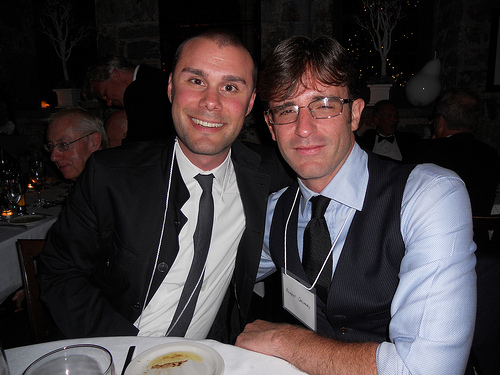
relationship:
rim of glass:
[21, 352, 50, 375] [21, 344, 115, 374]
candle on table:
[0, 208, 13, 218] [0, 179, 73, 302]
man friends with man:
[235, 36, 476, 374] [39, 24, 296, 346]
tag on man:
[280, 268, 317, 332] [235, 36, 476, 374]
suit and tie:
[36, 135, 298, 347] [166, 173, 216, 339]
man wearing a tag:
[235, 36, 476, 374] [280, 268, 317, 332]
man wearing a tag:
[39, 24, 296, 346] [137, 335, 170, 338]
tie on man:
[166, 173, 216, 339] [39, 24, 296, 346]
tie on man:
[303, 195, 332, 307] [235, 36, 476, 374]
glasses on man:
[265, 98, 353, 126] [235, 36, 476, 374]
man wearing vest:
[235, 36, 476, 374] [269, 151, 417, 354]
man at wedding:
[39, 24, 296, 346] [0, 0, 500, 375]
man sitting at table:
[39, 24, 296, 346] [2, 336, 308, 375]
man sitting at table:
[235, 36, 476, 374] [2, 336, 308, 375]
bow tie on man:
[376, 134, 398, 145] [357, 98, 423, 165]